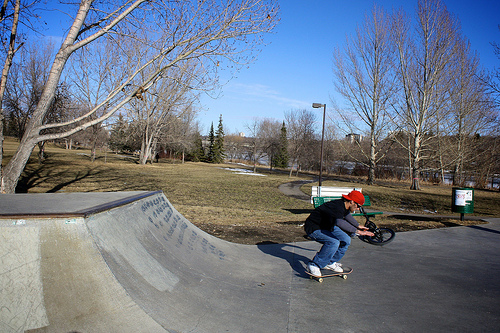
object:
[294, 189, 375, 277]
man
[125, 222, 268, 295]
concrete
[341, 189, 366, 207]
red hat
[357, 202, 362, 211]
dark sunglasses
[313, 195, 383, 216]
bench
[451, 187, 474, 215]
trash can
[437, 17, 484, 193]
trees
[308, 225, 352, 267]
blue jeans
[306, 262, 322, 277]
white shoes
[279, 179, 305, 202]
path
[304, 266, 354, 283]
skateboard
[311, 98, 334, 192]
light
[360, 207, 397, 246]
bike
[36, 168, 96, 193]
shadow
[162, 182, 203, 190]
grass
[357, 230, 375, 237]
hand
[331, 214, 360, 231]
arm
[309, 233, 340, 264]
leg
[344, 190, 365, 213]
head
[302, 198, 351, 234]
black tee shirt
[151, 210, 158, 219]
black characters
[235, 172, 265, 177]
snow